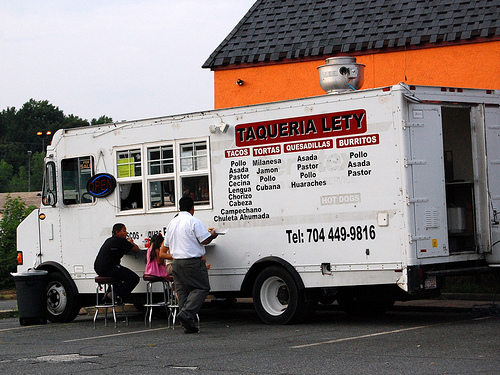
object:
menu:
[209, 107, 369, 228]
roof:
[200, 2, 500, 74]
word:
[346, 148, 371, 160]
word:
[346, 158, 371, 170]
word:
[345, 168, 375, 178]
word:
[288, 178, 332, 191]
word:
[254, 182, 284, 192]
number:
[367, 224, 379, 240]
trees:
[0, 96, 95, 180]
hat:
[86, 171, 119, 199]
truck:
[10, 56, 500, 324]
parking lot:
[0, 58, 500, 374]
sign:
[83, 172, 119, 201]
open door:
[413, 99, 498, 267]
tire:
[250, 264, 309, 326]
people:
[91, 223, 146, 316]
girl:
[143, 231, 180, 296]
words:
[318, 114, 366, 135]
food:
[213, 225, 228, 236]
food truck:
[13, 56, 500, 327]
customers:
[93, 221, 142, 306]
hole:
[29, 350, 102, 367]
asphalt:
[0, 295, 500, 374]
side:
[68, 128, 396, 252]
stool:
[90, 276, 130, 331]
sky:
[0, 2, 256, 123]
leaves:
[7, 197, 14, 203]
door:
[407, 103, 450, 261]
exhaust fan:
[315, 53, 367, 96]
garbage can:
[8, 267, 57, 327]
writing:
[289, 178, 331, 190]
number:
[306, 226, 313, 244]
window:
[111, 180, 145, 214]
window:
[143, 176, 181, 211]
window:
[174, 172, 211, 211]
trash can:
[11, 270, 54, 326]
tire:
[37, 270, 80, 325]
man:
[157, 195, 220, 334]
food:
[297, 153, 319, 165]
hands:
[212, 226, 218, 238]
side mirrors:
[40, 162, 62, 208]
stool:
[141, 270, 182, 328]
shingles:
[241, 35, 254, 42]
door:
[473, 102, 500, 256]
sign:
[230, 106, 371, 148]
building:
[200, 0, 500, 111]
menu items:
[225, 198, 256, 206]